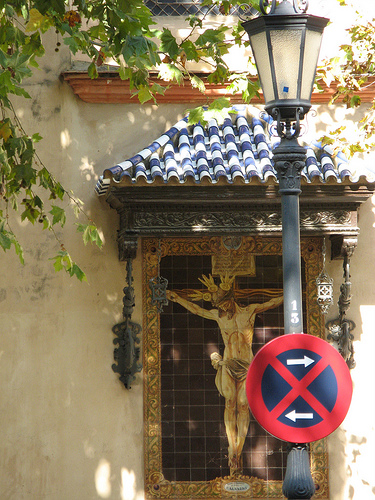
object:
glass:
[272, 31, 292, 70]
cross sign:
[246, 332, 354, 443]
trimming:
[144, 236, 163, 499]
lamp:
[242, 0, 328, 124]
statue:
[157, 270, 312, 481]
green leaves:
[2, 116, 71, 248]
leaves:
[81, 0, 129, 31]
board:
[63, 67, 375, 105]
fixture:
[111, 255, 143, 386]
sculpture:
[144, 235, 330, 499]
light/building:
[60, 122, 73, 152]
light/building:
[349, 301, 372, 497]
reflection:
[309, 124, 315, 139]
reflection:
[335, 106, 344, 120]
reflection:
[120, 468, 136, 498]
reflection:
[355, 304, 371, 422]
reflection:
[95, 459, 111, 496]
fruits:
[54, 41, 61, 52]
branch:
[36, 2, 113, 68]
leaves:
[195, 27, 225, 43]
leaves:
[139, 0, 151, 19]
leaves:
[156, 57, 185, 82]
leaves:
[188, 70, 204, 94]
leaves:
[343, 26, 375, 69]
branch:
[158, 19, 216, 77]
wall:
[0, 0, 373, 499]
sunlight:
[92, 455, 112, 498]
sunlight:
[118, 465, 138, 499]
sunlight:
[337, 302, 373, 498]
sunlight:
[58, 125, 72, 150]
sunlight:
[78, 154, 97, 180]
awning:
[94, 105, 375, 211]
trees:
[59, 13, 193, 57]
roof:
[147, 3, 249, 19]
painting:
[157, 248, 311, 482]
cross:
[155, 276, 284, 475]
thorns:
[186, 273, 237, 302]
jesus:
[165, 283, 283, 469]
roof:
[92, 106, 374, 198]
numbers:
[291, 299, 297, 311]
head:
[210, 287, 235, 313]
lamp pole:
[272, 137, 315, 499]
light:
[316, 272, 335, 312]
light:
[92, 455, 145, 498]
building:
[1, 0, 373, 497]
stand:
[272, 137, 316, 497]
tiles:
[101, 119, 372, 182]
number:
[291, 313, 299, 324]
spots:
[28, 266, 53, 300]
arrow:
[286, 355, 314, 368]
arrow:
[285, 409, 314, 422]